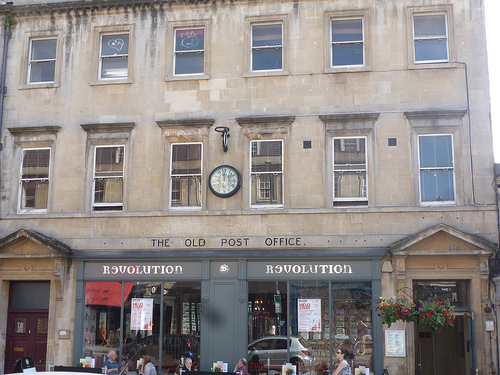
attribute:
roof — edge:
[26, 0, 84, 21]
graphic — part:
[130, 304, 159, 334]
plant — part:
[30, 330, 92, 352]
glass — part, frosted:
[257, 50, 284, 67]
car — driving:
[256, 335, 308, 357]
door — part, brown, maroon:
[104, 321, 165, 349]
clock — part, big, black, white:
[205, 163, 237, 198]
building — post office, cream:
[1, 15, 488, 240]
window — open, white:
[235, 11, 290, 74]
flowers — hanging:
[417, 308, 452, 329]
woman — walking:
[327, 338, 351, 374]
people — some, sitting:
[77, 343, 357, 371]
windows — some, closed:
[49, 41, 418, 83]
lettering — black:
[206, 230, 304, 245]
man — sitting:
[166, 353, 235, 367]